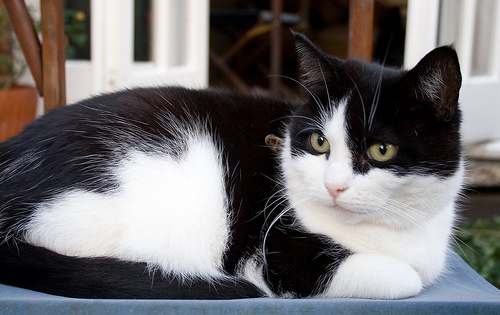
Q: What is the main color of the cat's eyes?
A: Yellow.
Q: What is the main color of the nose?
A: Pink.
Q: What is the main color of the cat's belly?
A: White.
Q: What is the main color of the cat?
A: Black.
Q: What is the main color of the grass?
A: Green.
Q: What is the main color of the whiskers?
A: White.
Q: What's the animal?
A: Cat.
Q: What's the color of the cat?
A: Black and white.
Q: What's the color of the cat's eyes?
A: Yellow.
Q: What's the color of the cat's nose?
A: Pink.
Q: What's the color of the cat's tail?
A: Black.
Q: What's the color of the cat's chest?
A: White.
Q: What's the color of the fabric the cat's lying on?
A: Blue.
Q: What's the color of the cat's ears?
A: Black.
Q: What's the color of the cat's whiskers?
A: White.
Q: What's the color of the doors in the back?
A: White.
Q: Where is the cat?
A: On a blue mat.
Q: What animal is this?
A: A cat.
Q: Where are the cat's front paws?
A: Tucked under the chest.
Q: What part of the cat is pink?
A: The nose.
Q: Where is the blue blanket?
A: Under the cat.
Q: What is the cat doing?
A: Lying down.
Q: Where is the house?
A: Behind the cat.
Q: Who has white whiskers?
A: The cat.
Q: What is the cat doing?
A: Lying.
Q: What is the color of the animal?
A: Black and white.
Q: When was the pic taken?
A: During the day.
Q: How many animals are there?
A: 1.